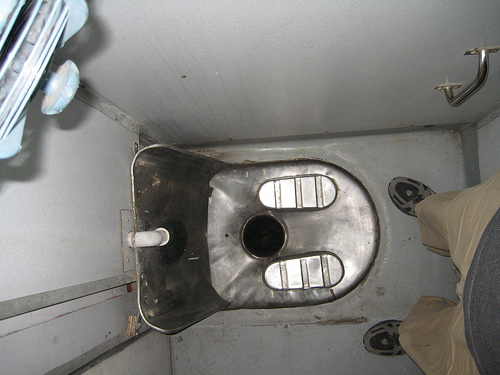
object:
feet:
[363, 319, 406, 356]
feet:
[388, 176, 437, 217]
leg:
[413, 184, 486, 256]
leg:
[395, 299, 453, 375]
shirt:
[463, 207, 500, 375]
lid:
[128, 144, 233, 337]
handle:
[432, 46, 500, 108]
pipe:
[128, 228, 171, 248]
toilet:
[128, 120, 480, 338]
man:
[362, 176, 499, 365]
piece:
[127, 313, 145, 338]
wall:
[154, 3, 411, 117]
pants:
[396, 172, 500, 374]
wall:
[40, 139, 122, 269]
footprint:
[263, 254, 344, 291]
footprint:
[257, 174, 338, 212]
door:
[74, 1, 499, 149]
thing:
[0, 0, 90, 156]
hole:
[241, 213, 285, 258]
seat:
[207, 159, 381, 310]